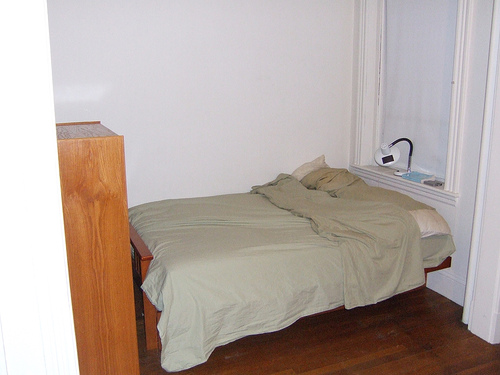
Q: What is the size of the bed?
A: Double.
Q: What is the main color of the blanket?
A: Light green.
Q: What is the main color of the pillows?
A: White.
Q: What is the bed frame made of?
A: Wood.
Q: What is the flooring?
A: Wood.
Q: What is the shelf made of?
A: Wood.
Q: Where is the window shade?
A: Pulled down.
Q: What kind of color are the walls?
A: White.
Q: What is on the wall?
A: Nothing.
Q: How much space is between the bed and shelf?
A: Very little.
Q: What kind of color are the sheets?
A: Light green.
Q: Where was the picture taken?
A: In a bedroom.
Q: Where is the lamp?
A: Windowsill.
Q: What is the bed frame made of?
A: Wood.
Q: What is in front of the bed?
A: A shelf.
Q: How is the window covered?
A: With a curtain.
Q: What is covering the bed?
A: A blanket.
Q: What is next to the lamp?
A: A book.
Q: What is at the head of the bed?
A: Pillows.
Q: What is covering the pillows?
A: Pillow cases.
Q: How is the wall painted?
A: White.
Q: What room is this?
A: Bedroom.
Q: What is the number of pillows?
A: 2.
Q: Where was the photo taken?
A: Bedroom.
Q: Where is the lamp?
A: On window sill.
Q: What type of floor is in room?
A: Wooden.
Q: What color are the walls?
A: White.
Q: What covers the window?
A: Curtain.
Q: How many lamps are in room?
A: 1.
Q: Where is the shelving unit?
A: At end of bed.